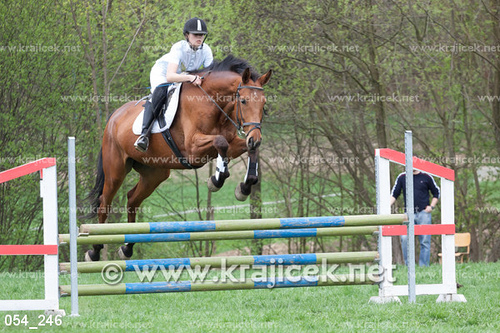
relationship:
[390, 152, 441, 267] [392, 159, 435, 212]
man in a shirt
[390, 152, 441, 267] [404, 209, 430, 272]
man in a jeans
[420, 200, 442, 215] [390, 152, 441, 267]
hand in pocket of man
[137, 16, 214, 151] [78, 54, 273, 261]
female riding a horse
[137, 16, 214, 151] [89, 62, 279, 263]
female on a horse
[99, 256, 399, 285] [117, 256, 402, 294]
text of a website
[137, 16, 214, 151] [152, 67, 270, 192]
female on a horse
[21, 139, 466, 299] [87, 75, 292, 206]
jump for horses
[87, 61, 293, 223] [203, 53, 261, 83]
horse with hair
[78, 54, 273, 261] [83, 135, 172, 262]
horse with hind legs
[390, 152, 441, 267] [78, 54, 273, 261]
man watching horse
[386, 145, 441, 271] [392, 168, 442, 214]
man with top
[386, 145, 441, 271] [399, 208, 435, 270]
man with jeans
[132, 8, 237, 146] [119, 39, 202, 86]
female in clothes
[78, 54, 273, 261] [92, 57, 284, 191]
horse with hair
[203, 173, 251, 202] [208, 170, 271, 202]
shoes of horse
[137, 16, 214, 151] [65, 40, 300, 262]
female on horse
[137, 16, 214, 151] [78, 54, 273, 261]
female on horse